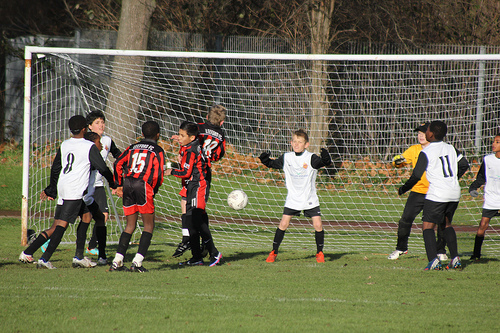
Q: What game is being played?
A: Soccer.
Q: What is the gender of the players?
A: Male.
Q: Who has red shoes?
A: Player in middle.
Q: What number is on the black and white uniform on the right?
A: 11.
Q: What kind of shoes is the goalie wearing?
A: Orange soccer shoes.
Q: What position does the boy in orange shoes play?
A: Goalie.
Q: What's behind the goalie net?
A: Trees.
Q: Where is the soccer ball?
A: In the net.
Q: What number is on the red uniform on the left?
A: 15.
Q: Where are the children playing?
A: ON soccer field.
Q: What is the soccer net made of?
A: Nylon cords.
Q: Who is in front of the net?
A: Soccer players.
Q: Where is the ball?
A: In the air between the players.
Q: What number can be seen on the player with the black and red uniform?
A: 15.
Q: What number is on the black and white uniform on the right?
A: 11.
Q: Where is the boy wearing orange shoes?
A: In the middle.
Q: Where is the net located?
A: Behind the boys.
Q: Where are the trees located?
A: Behind the net.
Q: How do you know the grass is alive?
A: It is green.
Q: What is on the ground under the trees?
A: Dried leaves.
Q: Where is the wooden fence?
A: Behind the soccer goal.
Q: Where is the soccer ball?
A: In the air.